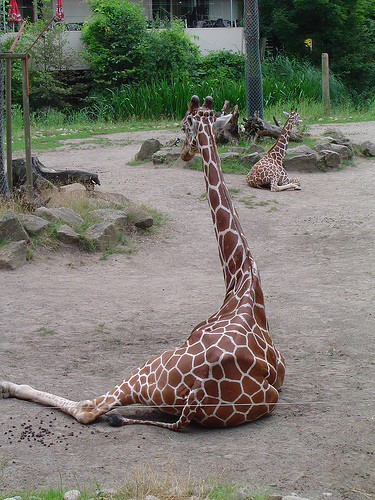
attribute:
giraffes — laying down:
[0, 93, 306, 433]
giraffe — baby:
[256, 116, 314, 202]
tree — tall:
[71, 8, 191, 103]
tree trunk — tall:
[242, 0, 265, 120]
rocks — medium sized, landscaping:
[1, 202, 152, 266]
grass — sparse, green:
[32, 128, 131, 151]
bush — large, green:
[74, 16, 198, 94]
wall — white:
[1, 26, 246, 70]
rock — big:
[317, 147, 340, 168]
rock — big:
[280, 150, 321, 173]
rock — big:
[134, 138, 160, 163]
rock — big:
[151, 143, 184, 166]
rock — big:
[52, 221, 80, 245]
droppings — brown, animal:
[4, 415, 75, 458]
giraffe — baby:
[247, 97, 311, 214]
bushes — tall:
[85, 8, 198, 123]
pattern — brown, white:
[191, 320, 264, 376]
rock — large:
[54, 206, 134, 257]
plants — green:
[152, 53, 267, 102]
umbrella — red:
[5, 1, 21, 27]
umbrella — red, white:
[5, 2, 23, 33]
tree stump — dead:
[248, 111, 309, 144]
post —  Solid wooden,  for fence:
[320, 51, 333, 121]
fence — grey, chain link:
[241, 0, 266, 124]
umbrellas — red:
[5, 2, 61, 26]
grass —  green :
[1, 194, 167, 274]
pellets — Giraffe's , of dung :
[0, 410, 145, 463]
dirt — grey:
[317, 189, 362, 244]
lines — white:
[143, 298, 234, 400]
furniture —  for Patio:
[195, 19, 221, 27]